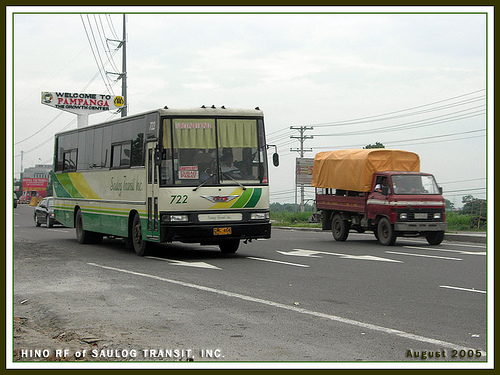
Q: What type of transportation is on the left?
A: Bus.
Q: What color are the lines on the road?
A: White.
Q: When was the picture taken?
A: August, 2005.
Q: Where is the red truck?
A: Right.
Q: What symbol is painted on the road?
A: Arrow.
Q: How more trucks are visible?
A: 1.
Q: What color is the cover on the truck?
A: Orange.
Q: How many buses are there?
A: 1.